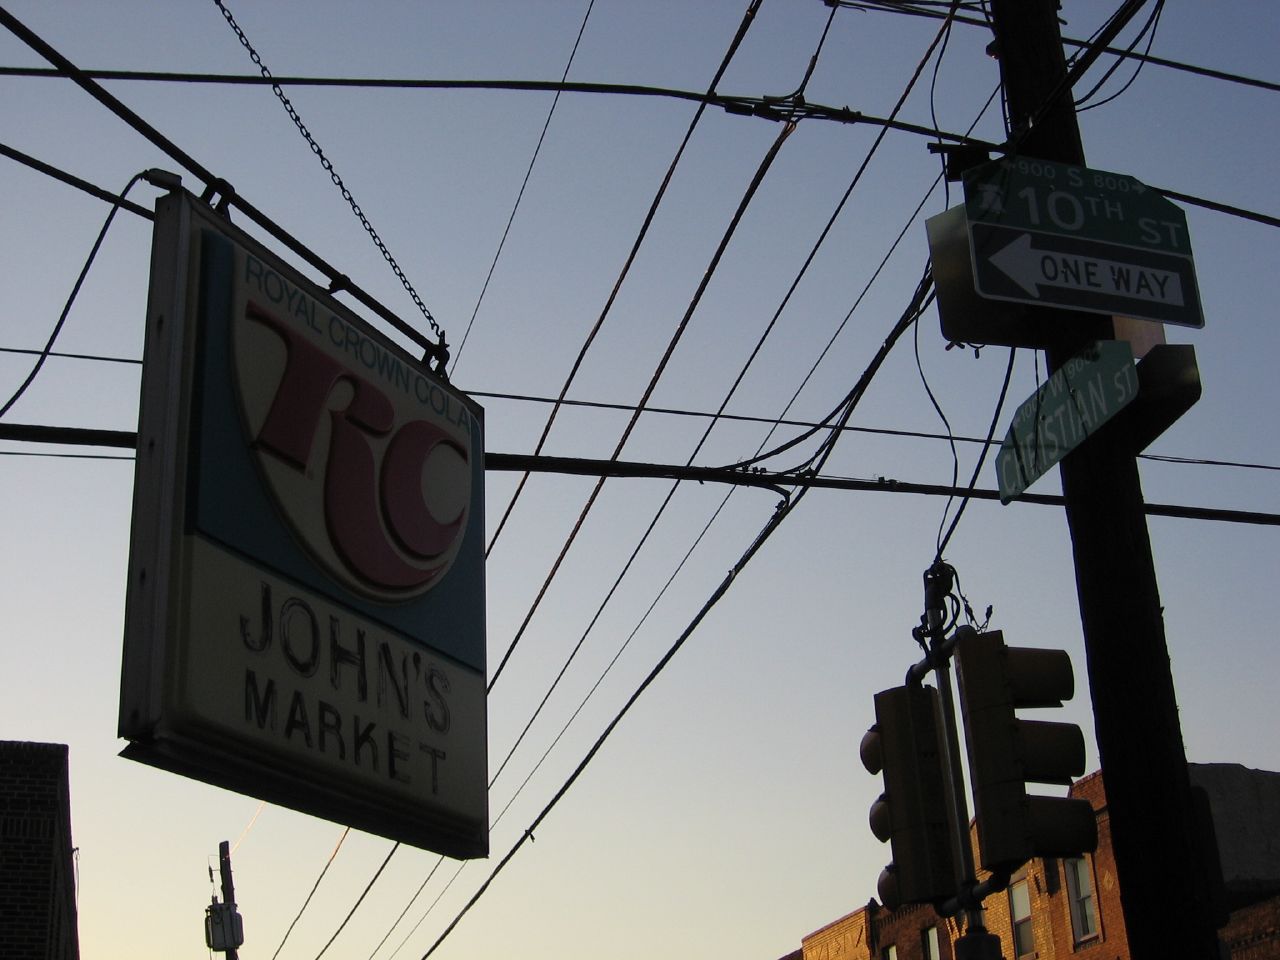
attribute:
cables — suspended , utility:
[229, 100, 862, 584]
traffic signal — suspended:
[821, 532, 1139, 955]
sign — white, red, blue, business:
[162, 202, 448, 851]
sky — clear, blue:
[574, 579, 799, 876]